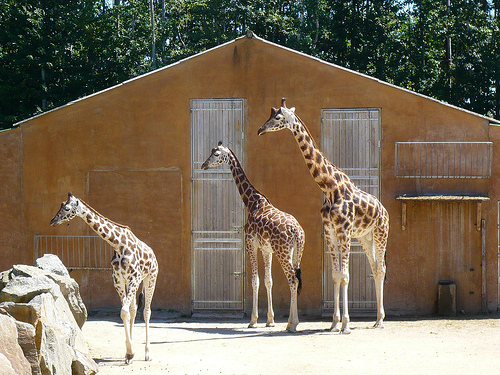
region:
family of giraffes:
[49, 96, 386, 365]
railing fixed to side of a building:
[395, 138, 491, 177]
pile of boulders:
[3, 250, 98, 373]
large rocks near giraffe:
[1, 252, 91, 374]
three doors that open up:
[188, 97, 245, 314]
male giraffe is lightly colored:
[258, 95, 388, 336]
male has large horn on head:
[258, 98, 389, 334]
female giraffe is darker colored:
[201, 140, 303, 333]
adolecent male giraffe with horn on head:
[51, 190, 158, 367]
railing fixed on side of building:
[31, 232, 117, 272]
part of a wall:
[409, 171, 421, 188]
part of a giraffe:
[370, 281, 382, 297]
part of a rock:
[71, 323, 89, 340]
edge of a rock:
[43, 305, 55, 327]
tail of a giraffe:
[301, 245, 306, 267]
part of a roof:
[383, 141, 411, 188]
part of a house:
[374, 159, 384, 176]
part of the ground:
[311, 324, 322, 344]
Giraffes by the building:
[51, 100, 391, 365]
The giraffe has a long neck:
[294, 127, 344, 191]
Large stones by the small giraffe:
[1, 253, 100, 372]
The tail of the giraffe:
[294, 235, 302, 289]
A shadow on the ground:
[115, 318, 327, 345]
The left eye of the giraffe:
[271, 114, 281, 119]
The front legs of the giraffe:
[247, 247, 277, 329]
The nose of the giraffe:
[256, 128, 261, 134]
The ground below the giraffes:
[6, 311, 498, 373]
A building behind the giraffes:
[3, 33, 498, 312]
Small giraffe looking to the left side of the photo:
[45, 187, 165, 372]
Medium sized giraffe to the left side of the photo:
[191, 127, 307, 332]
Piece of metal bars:
[389, 136, 494, 183]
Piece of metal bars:
[27, 230, 132, 273]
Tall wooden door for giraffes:
[189, 98, 247, 310]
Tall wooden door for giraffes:
[316, 110, 380, 315]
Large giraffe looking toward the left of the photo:
[260, 95, 402, 342]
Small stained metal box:
[425, 275, 468, 320]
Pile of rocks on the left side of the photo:
[0, 242, 99, 373]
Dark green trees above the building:
[0, 0, 499, 123]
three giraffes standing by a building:
[49, 96, 392, 353]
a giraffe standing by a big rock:
[22, 186, 162, 367]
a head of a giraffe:
[250, 92, 300, 140]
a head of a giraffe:
[195, 137, 232, 176]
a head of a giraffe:
[48, 187, 85, 229]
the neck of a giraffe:
[79, 207, 129, 253]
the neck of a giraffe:
[227, 147, 254, 201]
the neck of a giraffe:
[289, 104, 336, 189]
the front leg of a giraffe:
[335, 227, 356, 333]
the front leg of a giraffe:
[249, 237, 263, 332]